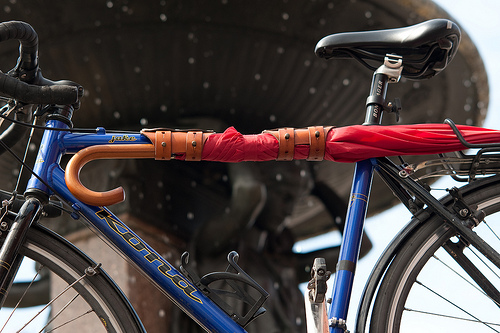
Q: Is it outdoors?
A: Yes, it is outdoors.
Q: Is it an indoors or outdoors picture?
A: It is outdoors.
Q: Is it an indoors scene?
A: No, it is outdoors.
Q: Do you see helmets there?
A: No, there are no helmets.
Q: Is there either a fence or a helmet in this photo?
A: No, there are no helmets or fences.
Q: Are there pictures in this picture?
A: No, there are no pictures.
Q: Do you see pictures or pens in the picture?
A: No, there are no pictures or pens.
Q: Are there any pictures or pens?
A: No, there are no pictures or pens.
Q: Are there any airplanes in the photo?
A: No, there are no airplanes.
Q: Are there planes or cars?
A: No, there are no planes or cars.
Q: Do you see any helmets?
A: No, there are no helmets.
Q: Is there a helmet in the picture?
A: No, there are no helmets.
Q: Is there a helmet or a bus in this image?
A: No, there are no helmets or buses.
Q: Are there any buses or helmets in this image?
A: No, there are no helmets or buses.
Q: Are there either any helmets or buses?
A: No, there are no helmets or buses.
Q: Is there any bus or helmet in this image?
A: No, there are no helmets or buses.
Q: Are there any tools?
A: No, there are no tools.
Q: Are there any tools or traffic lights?
A: No, there are no tools or traffic lights.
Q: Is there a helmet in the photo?
A: No, there are no helmets.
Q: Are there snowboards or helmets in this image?
A: No, there are no helmets or snowboards.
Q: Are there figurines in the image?
A: No, there are no figurines.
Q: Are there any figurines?
A: No, there are no figurines.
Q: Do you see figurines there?
A: No, there are no figurines.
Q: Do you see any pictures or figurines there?
A: No, there are no figurines or pictures.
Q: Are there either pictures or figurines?
A: No, there are no figurines or pictures.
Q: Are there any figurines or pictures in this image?
A: No, there are no figurines or pictures.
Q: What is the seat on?
A: The seat is on the bike.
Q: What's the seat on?
A: The seat is on the bike.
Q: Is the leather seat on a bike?
A: Yes, the seat is on a bike.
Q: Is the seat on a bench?
A: No, the seat is on a bike.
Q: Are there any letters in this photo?
A: Yes, there are letters.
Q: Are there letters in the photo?
A: Yes, there are letters.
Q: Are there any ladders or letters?
A: Yes, there are letters.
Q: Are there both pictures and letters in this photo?
A: No, there are letters but no pictures.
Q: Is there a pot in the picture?
A: No, there are no pots.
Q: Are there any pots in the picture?
A: No, there are no pots.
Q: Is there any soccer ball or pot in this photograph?
A: No, there are no pots or soccer balls.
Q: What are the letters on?
A: The letters are on the bike.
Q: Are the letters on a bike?
A: Yes, the letters are on a bike.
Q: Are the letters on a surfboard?
A: No, the letters are on a bike.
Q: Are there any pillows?
A: No, there are no pillows.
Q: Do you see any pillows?
A: No, there are no pillows.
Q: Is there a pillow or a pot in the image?
A: No, there are no pillows or pots.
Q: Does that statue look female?
A: Yes, the statue is female.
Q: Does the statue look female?
A: Yes, the statue is female.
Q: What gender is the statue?
A: The statue is female.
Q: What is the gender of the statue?
A: The statue is female.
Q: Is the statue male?
A: No, the statue is female.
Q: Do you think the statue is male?
A: No, the statue is female.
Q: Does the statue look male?
A: No, the statue is female.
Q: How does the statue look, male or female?
A: The statue is female.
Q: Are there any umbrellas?
A: Yes, there is an umbrella.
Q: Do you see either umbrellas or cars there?
A: Yes, there is an umbrella.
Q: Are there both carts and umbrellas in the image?
A: No, there is an umbrella but no carts.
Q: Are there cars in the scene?
A: No, there are no cars.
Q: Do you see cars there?
A: No, there are no cars.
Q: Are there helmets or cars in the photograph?
A: No, there are no cars or helmets.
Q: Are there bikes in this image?
A: Yes, there is a bike.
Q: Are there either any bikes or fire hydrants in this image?
A: Yes, there is a bike.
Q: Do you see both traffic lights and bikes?
A: No, there is a bike but no traffic lights.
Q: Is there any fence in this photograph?
A: No, there are no fences.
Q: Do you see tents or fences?
A: No, there are no fences or tents.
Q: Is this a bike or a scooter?
A: This is a bike.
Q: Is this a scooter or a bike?
A: This is a bike.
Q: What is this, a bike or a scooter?
A: This is a bike.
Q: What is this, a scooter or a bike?
A: This is a bike.